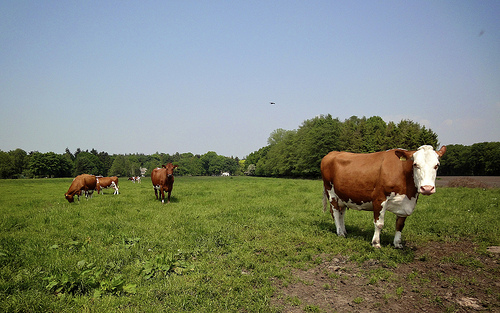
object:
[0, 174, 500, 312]
grass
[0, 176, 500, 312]
field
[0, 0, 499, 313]
scene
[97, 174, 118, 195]
cow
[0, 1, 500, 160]
sky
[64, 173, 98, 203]
cow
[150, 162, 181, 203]
cow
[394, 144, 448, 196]
head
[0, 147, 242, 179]
trees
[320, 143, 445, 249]
cow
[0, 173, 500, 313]
ground